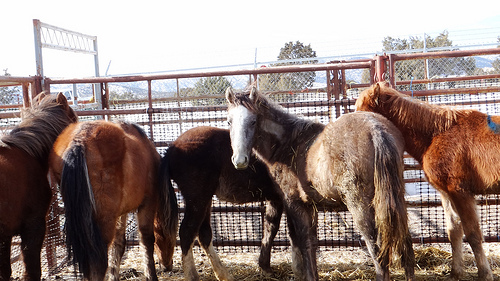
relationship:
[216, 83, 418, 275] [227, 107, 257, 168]
horse with face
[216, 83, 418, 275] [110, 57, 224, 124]
horse in front of a fence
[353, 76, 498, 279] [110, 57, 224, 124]
horse in front of a fence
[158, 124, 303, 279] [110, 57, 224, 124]
horse in front of a fence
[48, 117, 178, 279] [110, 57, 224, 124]
horse in front of a fence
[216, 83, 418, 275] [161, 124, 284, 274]
horse standing in front of another horse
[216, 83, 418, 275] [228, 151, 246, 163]
horse with a nose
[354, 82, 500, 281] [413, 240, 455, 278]
horse are eating hay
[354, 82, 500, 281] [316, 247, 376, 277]
horse are eating hay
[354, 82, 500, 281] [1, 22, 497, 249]
horse in enclosure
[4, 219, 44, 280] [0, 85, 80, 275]
legs of horse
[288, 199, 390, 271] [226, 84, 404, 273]
legs of horse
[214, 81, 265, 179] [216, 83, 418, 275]
head on horse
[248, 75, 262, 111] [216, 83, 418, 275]
ear on horse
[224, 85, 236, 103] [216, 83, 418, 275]
ear on horse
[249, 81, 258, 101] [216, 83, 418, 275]
ear on horse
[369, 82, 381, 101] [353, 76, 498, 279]
ear on horse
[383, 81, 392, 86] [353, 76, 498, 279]
ear on horse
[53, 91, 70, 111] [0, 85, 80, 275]
ear on horse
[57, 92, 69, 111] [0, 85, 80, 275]
ear on horse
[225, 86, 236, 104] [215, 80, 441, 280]
ear on horse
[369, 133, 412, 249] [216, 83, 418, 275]
tail on horse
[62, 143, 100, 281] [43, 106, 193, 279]
tail on horse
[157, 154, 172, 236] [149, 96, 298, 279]
tail on horse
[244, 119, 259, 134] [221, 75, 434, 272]
eye on horse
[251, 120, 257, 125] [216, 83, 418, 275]
eye on horse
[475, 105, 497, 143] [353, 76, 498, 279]
print on horse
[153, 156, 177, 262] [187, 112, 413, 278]
tail of horse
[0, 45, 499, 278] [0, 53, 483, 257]
horses behind fence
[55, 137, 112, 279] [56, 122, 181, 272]
tail of horse